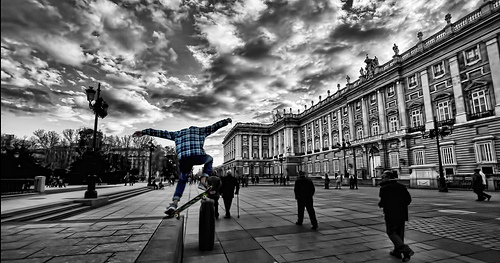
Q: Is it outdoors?
A: Yes, it is outdoors.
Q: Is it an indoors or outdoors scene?
A: It is outdoors.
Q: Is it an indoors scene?
A: No, it is outdoors.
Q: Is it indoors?
A: No, it is outdoors.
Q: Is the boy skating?
A: Yes, the boy is skating.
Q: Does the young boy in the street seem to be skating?
A: Yes, the boy is skating.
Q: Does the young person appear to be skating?
A: Yes, the boy is skating.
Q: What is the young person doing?
A: The boy is skating.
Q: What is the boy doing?
A: The boy is skating.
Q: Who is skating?
A: The boy is skating.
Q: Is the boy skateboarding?
A: No, the boy is skating.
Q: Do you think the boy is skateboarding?
A: No, the boy is skating.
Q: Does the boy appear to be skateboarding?
A: No, the boy is skating.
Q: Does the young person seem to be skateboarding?
A: No, the boy is skating.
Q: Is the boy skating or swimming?
A: The boy is skating.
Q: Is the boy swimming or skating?
A: The boy is skating.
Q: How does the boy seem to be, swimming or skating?
A: The boy is skating.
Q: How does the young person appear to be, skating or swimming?
A: The boy is skating.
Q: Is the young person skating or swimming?
A: The boy is skating.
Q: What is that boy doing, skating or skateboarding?
A: The boy is skating.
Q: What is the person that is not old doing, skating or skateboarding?
A: The boy is skating.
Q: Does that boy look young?
A: Yes, the boy is young.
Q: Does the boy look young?
A: Yes, the boy is young.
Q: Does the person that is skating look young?
A: Yes, the boy is young.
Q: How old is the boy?
A: The boy is young.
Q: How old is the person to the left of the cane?
A: The boy is young.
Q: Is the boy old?
A: No, the boy is young.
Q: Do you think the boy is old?
A: No, the boy is young.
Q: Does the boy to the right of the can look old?
A: No, the boy is young.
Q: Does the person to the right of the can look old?
A: No, the boy is young.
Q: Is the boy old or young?
A: The boy is young.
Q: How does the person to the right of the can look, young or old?
A: The boy is young.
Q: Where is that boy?
A: The boy is in the street.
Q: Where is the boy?
A: The boy is in the street.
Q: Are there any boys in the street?
A: Yes, there is a boy in the street.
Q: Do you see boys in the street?
A: Yes, there is a boy in the street.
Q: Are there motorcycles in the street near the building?
A: No, there is a boy in the street.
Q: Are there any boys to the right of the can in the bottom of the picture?
A: Yes, there is a boy to the right of the can.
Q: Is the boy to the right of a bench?
A: No, the boy is to the right of the can.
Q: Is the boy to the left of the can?
A: No, the boy is to the right of the can.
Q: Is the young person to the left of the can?
A: No, the boy is to the right of the can.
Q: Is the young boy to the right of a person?
A: No, the boy is to the left of a person.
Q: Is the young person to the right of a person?
A: No, the boy is to the left of a person.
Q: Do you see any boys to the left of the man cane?
A: Yes, there is a boy to the left of the cane.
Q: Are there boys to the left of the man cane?
A: Yes, there is a boy to the left of the cane.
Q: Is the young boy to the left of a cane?
A: Yes, the boy is to the left of a cane.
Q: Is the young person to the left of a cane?
A: Yes, the boy is to the left of a cane.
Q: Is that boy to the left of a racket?
A: No, the boy is to the left of a cane.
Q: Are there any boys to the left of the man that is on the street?
A: Yes, there is a boy to the left of the man.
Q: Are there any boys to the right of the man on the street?
A: No, the boy is to the left of the man.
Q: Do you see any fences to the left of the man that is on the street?
A: No, there is a boy to the left of the man.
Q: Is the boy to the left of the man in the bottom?
A: Yes, the boy is to the left of the man.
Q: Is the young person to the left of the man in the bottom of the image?
A: Yes, the boy is to the left of the man.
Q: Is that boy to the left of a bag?
A: No, the boy is to the left of the man.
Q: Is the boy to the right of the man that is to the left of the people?
A: No, the boy is to the left of the man.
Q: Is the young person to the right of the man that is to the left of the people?
A: No, the boy is to the left of the man.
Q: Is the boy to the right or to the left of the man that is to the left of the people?
A: The boy is to the left of the man.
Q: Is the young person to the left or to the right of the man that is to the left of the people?
A: The boy is to the left of the man.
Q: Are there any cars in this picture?
A: No, there are no cars.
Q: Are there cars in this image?
A: No, there are no cars.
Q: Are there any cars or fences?
A: No, there are no cars or fences.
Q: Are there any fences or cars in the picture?
A: No, there are no cars or fences.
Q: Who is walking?
A: The people are walking.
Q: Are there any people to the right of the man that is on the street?
A: Yes, there are people to the right of the man.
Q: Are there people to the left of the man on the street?
A: No, the people are to the right of the man.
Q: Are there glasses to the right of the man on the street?
A: No, there are people to the right of the man.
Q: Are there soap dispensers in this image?
A: No, there are no soap dispensers.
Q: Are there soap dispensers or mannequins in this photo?
A: No, there are no soap dispensers or mannequins.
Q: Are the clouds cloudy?
A: Yes, the clouds are cloudy.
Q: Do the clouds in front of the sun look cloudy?
A: Yes, the clouds are cloudy.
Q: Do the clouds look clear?
A: No, the clouds are cloudy.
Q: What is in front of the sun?
A: The clouds are in front of the sun.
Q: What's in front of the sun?
A: The clouds are in front of the sun.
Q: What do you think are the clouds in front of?
A: The clouds are in front of the sun.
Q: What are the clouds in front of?
A: The clouds are in front of the sun.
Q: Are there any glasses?
A: No, there are no glasses.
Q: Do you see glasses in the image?
A: No, there are no glasses.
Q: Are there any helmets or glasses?
A: No, there are no glasses or helmets.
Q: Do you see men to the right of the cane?
A: Yes, there is a man to the right of the cane.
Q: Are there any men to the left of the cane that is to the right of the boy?
A: No, the man is to the right of the cane.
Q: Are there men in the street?
A: Yes, there is a man in the street.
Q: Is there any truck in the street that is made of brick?
A: No, there is a man in the street.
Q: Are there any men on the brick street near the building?
A: Yes, there is a man on the street.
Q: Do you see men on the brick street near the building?
A: Yes, there is a man on the street.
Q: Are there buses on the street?
A: No, there is a man on the street.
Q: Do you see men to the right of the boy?
A: Yes, there is a man to the right of the boy.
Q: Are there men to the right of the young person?
A: Yes, there is a man to the right of the boy.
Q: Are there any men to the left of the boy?
A: No, the man is to the right of the boy.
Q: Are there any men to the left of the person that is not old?
A: No, the man is to the right of the boy.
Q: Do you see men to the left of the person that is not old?
A: No, the man is to the right of the boy.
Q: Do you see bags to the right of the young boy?
A: No, there is a man to the right of the boy.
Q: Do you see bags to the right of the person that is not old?
A: No, there is a man to the right of the boy.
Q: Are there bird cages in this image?
A: No, there are no bird cages.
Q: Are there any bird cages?
A: No, there are no bird cages.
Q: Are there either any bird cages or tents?
A: No, there are no bird cages or tents.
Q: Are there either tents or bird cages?
A: No, there are no bird cages or tents.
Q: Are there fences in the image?
A: No, there are no fences.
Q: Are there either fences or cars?
A: No, there are no fences or cars.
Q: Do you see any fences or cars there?
A: No, there are no fences or cars.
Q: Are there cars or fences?
A: No, there are no fences or cars.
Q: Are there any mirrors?
A: No, there are no mirrors.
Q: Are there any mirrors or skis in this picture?
A: No, there are no mirrors or skis.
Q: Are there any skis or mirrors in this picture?
A: No, there are no mirrors or skis.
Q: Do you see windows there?
A: Yes, there are windows.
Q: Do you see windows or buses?
A: Yes, there are windows.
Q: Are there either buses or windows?
A: Yes, there are windows.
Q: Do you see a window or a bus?
A: Yes, there are windows.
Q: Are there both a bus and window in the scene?
A: No, there are windows but no buses.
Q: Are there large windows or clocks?
A: Yes, there are large windows.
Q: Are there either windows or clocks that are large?
A: Yes, the windows are large.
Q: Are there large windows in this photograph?
A: Yes, there are large windows.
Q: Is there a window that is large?
A: Yes, there are windows that are large.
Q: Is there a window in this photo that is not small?
A: Yes, there are large windows.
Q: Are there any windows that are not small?
A: Yes, there are large windows.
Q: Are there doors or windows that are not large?
A: No, there are windows but they are large.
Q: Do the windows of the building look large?
A: Yes, the windows are large.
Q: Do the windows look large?
A: Yes, the windows are large.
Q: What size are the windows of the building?
A: The windows are large.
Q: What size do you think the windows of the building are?
A: The windows are large.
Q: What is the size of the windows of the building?
A: The windows are large.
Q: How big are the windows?
A: The windows are large.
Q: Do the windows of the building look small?
A: No, the windows are large.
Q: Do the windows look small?
A: No, the windows are large.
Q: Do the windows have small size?
A: No, the windows are large.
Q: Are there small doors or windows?
A: No, there are windows but they are large.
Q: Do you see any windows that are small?
A: No, there are windows but they are large.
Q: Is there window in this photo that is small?
A: No, there are windows but they are large.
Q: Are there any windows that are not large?
A: No, there are windows but they are large.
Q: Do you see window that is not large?
A: No, there are windows but they are large.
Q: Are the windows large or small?
A: The windows are large.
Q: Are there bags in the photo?
A: No, there are no bags.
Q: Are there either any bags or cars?
A: No, there are no bags or cars.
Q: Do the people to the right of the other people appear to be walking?
A: Yes, the people are walking.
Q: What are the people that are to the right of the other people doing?
A: The people are walking.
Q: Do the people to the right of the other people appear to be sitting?
A: No, the people are walking.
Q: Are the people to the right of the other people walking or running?
A: The people are walking.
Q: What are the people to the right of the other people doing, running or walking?
A: The people are walking.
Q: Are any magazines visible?
A: No, there are no magazines.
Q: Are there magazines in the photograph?
A: No, there are no magazines.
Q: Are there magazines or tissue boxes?
A: No, there are no magazines or tissue boxes.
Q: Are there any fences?
A: No, there are no fences.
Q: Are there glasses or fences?
A: No, there are no fences or glasses.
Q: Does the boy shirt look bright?
A: Yes, the shirt is bright.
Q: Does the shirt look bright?
A: Yes, the shirt is bright.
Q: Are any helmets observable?
A: No, there are no helmets.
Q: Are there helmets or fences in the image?
A: No, there are no helmets or fences.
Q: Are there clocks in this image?
A: No, there are no clocks.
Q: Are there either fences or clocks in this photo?
A: No, there are no clocks or fences.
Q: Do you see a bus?
A: No, there are no buses.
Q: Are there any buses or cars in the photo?
A: No, there are no buses or cars.